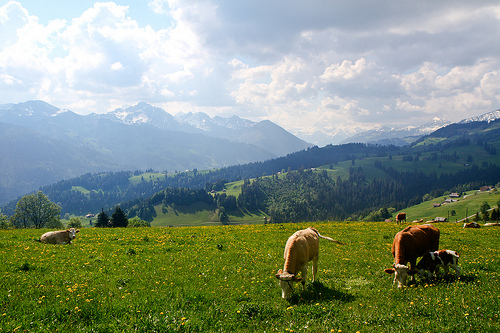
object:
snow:
[6, 100, 494, 147]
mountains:
[0, 97, 500, 202]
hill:
[0, 111, 500, 332]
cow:
[272, 227, 344, 302]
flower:
[66, 287, 77, 294]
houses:
[479, 185, 489, 191]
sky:
[0, 0, 500, 139]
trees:
[237, 176, 260, 210]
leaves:
[280, 193, 294, 205]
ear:
[294, 276, 302, 283]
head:
[273, 271, 303, 302]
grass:
[0, 125, 500, 333]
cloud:
[0, 0, 500, 130]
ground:
[0, 222, 500, 333]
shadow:
[287, 282, 358, 307]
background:
[0, 0, 499, 225]